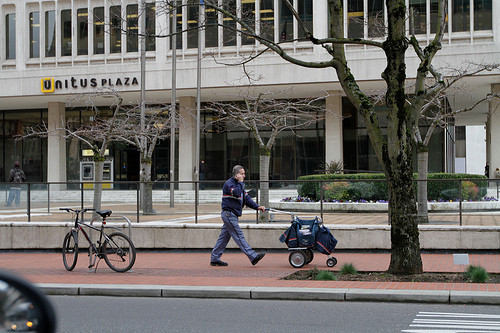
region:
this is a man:
[206, 155, 262, 264]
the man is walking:
[208, 165, 258, 266]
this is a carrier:
[277, 215, 337, 267]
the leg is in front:
[234, 227, 269, 264]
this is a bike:
[50, 205, 135, 270]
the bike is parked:
[54, 209, 133, 268]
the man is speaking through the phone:
[231, 173, 245, 182]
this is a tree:
[376, 114, 428, 278]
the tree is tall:
[368, 47, 436, 260]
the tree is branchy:
[323, 15, 454, 152]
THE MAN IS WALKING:
[194, 155, 268, 270]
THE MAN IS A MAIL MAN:
[198, 154, 265, 275]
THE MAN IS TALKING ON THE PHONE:
[192, 158, 278, 270]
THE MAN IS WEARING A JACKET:
[213, 174, 265, 221]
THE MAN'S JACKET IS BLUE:
[216, 177, 262, 222]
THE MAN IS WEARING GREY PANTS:
[195, 206, 265, 281]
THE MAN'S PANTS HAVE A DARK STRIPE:
[202, 205, 264, 268]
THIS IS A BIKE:
[51, 200, 143, 279]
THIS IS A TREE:
[82, 0, 499, 288]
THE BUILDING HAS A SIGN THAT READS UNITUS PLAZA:
[33, 70, 145, 97]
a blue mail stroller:
[277, 198, 345, 277]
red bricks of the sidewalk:
[146, 261, 288, 283]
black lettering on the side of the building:
[35, 71, 145, 90]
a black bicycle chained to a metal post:
[46, 203, 144, 280]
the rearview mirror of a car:
[1, 251, 84, 331]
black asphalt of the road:
[33, 303, 410, 330]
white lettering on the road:
[387, 304, 497, 331]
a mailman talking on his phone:
[206, 164, 279, 277]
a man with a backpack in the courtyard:
[1, 160, 40, 215]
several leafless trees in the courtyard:
[29, 25, 465, 221]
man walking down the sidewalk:
[199, 163, 272, 270]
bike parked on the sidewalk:
[51, 202, 136, 275]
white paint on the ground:
[394, 303, 499, 331]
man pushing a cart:
[201, 161, 350, 273]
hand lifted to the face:
[233, 171, 243, 181]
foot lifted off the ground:
[248, 249, 269, 267]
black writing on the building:
[37, 73, 144, 90]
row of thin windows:
[0, 2, 499, 64]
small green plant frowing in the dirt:
[464, 261, 490, 281]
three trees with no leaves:
[32, 89, 307, 219]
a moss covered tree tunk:
[364, 1, 429, 276]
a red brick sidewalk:
[0, 241, 499, 300]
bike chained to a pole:
[56, 200, 140, 275]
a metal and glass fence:
[10, 174, 498, 233]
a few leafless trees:
[38, 83, 449, 220]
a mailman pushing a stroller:
[210, 163, 350, 270]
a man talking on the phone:
[208, 160, 268, 267]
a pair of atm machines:
[80, 146, 114, 188]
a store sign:
[41, 75, 141, 91]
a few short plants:
[461, 262, 493, 285]